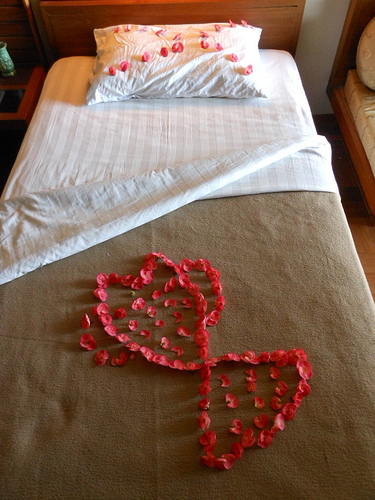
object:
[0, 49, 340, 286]
sheets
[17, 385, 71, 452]
indention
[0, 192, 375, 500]
bedspread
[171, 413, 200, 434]
shadows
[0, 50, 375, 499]
bed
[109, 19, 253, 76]
flowers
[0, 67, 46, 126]
nightstand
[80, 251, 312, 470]
flowers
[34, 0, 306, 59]
headboard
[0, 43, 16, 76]
vase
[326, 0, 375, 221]
bed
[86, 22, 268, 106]
pillow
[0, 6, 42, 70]
stand